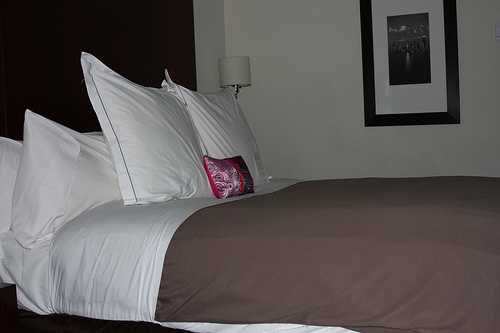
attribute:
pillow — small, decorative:
[202, 151, 259, 198]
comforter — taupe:
[186, 176, 486, 330]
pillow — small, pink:
[204, 155, 254, 200]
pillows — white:
[163, 71, 270, 193]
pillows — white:
[81, 50, 217, 205]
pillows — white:
[11, 109, 123, 248]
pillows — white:
[0, 137, 22, 233]